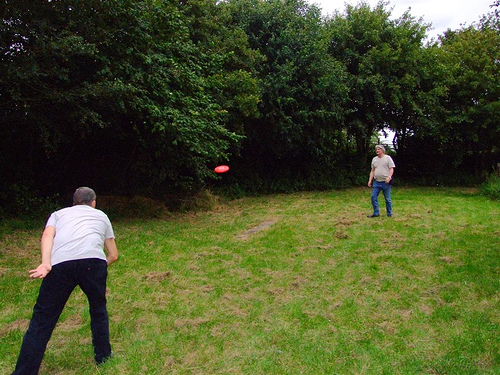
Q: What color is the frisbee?
A: Red.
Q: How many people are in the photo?
A: Two.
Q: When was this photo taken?
A: During the day.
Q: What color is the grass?
A: Green and brown.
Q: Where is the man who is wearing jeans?
A: In the background facing the camera.